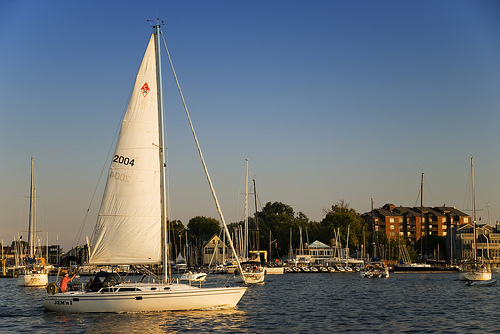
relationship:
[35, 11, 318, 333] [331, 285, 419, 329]
boat on water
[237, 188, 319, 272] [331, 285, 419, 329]
tree near water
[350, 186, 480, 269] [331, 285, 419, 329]
building near water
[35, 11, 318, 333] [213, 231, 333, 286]
boat in harbor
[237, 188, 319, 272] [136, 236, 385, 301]
tree on shoreline